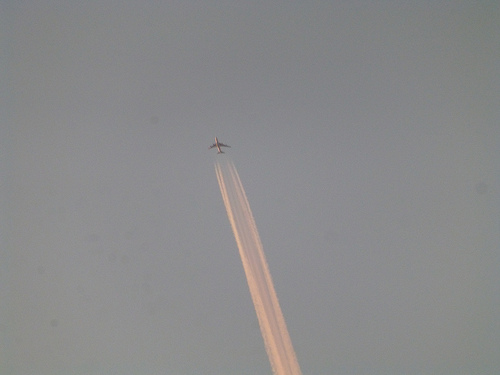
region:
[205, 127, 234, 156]
large commercial passenger plane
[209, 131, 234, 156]
big ol' jet airliner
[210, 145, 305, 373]
four cloudy streams left by jet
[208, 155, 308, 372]
pale orange exhaust from plane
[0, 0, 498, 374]
hazy grey sky with no clouds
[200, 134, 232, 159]
grey air plane in the distance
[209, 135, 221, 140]
front of jet airliner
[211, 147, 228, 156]
tail of jet airliner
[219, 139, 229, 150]
left side of plane wing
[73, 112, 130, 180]
The sky is clear.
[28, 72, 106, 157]
The sky is gray.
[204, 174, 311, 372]
The smoke is white.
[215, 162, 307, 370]
The smoke is coming from the airplane.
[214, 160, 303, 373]
The smoke is in the sky.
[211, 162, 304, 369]
The smoke tail is long.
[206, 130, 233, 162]
The plane is in the sky.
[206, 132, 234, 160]
The plane is flying.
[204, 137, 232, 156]
The plane is made of metal.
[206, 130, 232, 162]
The bottom of the plane is showing.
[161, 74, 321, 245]
an airplane outside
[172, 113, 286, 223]
a plane in the sky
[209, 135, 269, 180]
an airplane flying in the sky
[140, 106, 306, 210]
a plane flying in the sky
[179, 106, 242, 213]
an airplane in the air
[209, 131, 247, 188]
a plane flying in the air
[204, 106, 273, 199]
a plane flying in the air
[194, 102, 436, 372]
a plane creating smoke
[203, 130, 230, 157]
Plane in the air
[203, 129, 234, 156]
Plane is in the air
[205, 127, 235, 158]
Airplane in the air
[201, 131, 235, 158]
Airplane is in the air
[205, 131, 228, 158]
Plane flying in the air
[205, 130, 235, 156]
Plane is flying in the air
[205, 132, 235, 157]
Airplane flying in the air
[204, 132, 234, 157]
Airplane is flying in the air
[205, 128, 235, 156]
Plane up in the air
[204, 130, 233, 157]
Airplane is up in the air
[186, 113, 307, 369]
airplane flying upward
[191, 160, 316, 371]
fumes from the plane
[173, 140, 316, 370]
plane ascending upward after takeoff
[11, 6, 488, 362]
dark grey sky with no clouds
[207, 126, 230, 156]
grey plane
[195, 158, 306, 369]
fumes appear slightly orange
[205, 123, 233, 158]
plane is in middle of image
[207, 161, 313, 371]
two streams are coming from two engines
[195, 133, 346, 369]
plane ascending at slight diagonal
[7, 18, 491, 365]
a dark evening sky